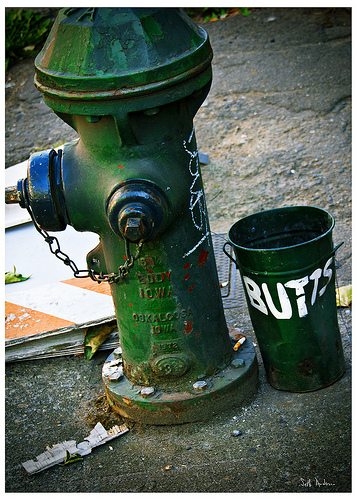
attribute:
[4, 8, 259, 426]
hydrant — green, old, rusty, painted, large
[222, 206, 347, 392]
trash can — green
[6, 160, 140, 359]
construction stand — white, orange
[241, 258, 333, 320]
writing — white, painted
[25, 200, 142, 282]
chain — draping, hanging, large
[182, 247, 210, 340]
rust — red, brown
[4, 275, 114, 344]
stripes — orange, white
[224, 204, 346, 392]
bucket — green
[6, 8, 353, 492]
sidewalk — old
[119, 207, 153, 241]
bolt — large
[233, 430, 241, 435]
pebble — white, small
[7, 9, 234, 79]
bush — green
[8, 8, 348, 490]
ground — cement